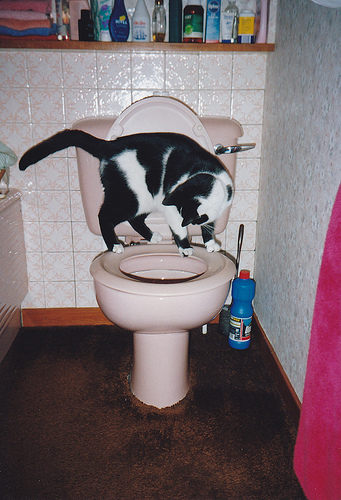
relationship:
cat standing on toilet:
[20, 125, 236, 257] [75, 117, 238, 410]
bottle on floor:
[230, 269, 256, 351] [1, 323, 307, 498]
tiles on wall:
[5, 26, 271, 314] [3, 3, 340, 415]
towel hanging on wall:
[288, 174, 338, 499] [3, 3, 340, 415]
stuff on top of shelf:
[4, 3, 265, 43] [3, 37, 276, 55]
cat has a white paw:
[20, 125, 236, 257] [205, 237, 220, 255]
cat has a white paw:
[20, 125, 236, 257] [149, 230, 163, 245]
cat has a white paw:
[20, 125, 236, 257] [178, 247, 196, 259]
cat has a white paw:
[20, 125, 236, 257] [112, 241, 126, 255]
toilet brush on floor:
[216, 216, 244, 340] [1, 323, 307, 498]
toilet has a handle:
[75, 117, 238, 410] [216, 143, 256, 155]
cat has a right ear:
[20, 125, 236, 257] [161, 188, 175, 208]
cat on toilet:
[20, 125, 236, 257] [75, 117, 238, 410]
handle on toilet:
[216, 143, 256, 155] [75, 117, 238, 410]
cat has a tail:
[20, 125, 236, 257] [20, 128, 102, 169]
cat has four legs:
[20, 125, 236, 257] [94, 213, 221, 249]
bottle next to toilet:
[230, 269, 256, 351] [75, 117, 238, 410]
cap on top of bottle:
[240, 269, 252, 281] [230, 269, 256, 351]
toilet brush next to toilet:
[216, 216, 244, 340] [75, 117, 238, 410]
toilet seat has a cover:
[90, 243, 237, 296] [105, 97, 217, 242]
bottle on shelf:
[110, 0, 130, 41] [3, 37, 276, 55]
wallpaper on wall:
[253, 4, 340, 407] [3, 3, 340, 415]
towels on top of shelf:
[0, 0, 60, 39] [3, 37, 276, 55]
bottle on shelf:
[134, 0, 150, 44] [3, 37, 276, 55]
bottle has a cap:
[230, 269, 256, 351] [240, 269, 252, 281]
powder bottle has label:
[236, 9, 260, 46] [237, 15, 256, 36]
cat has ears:
[20, 125, 236, 257] [163, 195, 197, 227]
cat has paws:
[20, 125, 236, 257] [100, 233, 222, 258]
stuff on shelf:
[4, 3, 265, 43] [3, 37, 276, 55]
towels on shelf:
[0, 0, 60, 39] [3, 37, 276, 55]